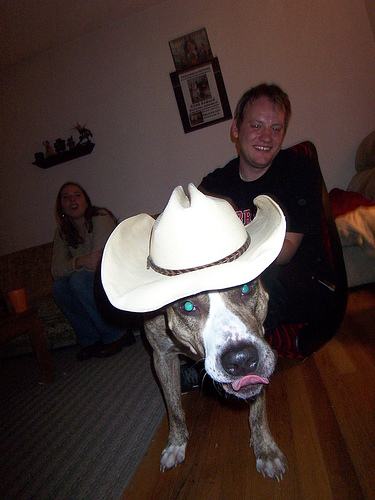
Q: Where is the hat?
A: On dog.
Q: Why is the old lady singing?
A: No old lady.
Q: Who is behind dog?
A: A man.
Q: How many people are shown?
A: Two.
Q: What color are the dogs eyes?
A: Blue.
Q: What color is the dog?
A: Brown and white.